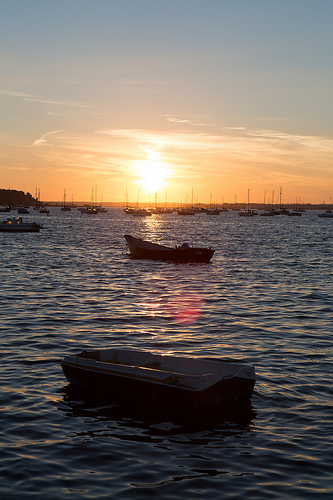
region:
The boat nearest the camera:
[57, 341, 260, 410]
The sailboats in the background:
[0, 183, 332, 221]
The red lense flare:
[162, 288, 209, 328]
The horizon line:
[1, 185, 332, 208]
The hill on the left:
[0, 187, 47, 208]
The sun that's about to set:
[120, 138, 178, 200]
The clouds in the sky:
[0, 73, 332, 192]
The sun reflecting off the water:
[136, 206, 173, 346]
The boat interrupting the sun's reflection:
[120, 230, 217, 264]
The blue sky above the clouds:
[0, 0, 332, 143]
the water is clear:
[226, 466, 237, 478]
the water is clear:
[207, 473, 218, 484]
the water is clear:
[209, 477, 221, 497]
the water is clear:
[218, 479, 222, 490]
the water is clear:
[202, 474, 216, 496]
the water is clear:
[204, 479, 210, 486]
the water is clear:
[201, 479, 206, 487]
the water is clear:
[197, 469, 202, 478]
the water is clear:
[191, 481, 198, 489]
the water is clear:
[211, 467, 218, 487]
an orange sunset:
[2, 0, 332, 203]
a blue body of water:
[2, 201, 327, 491]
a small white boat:
[64, 339, 250, 417]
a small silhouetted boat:
[119, 228, 218, 266]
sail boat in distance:
[79, 184, 94, 212]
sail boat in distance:
[93, 188, 104, 209]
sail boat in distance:
[119, 185, 130, 210]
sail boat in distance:
[131, 184, 145, 215]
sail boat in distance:
[149, 188, 159, 210]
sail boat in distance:
[178, 192, 190, 213]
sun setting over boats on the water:
[117, 148, 189, 219]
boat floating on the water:
[47, 340, 263, 414]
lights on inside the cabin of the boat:
[0, 213, 39, 231]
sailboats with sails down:
[122, 187, 230, 216]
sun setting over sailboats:
[111, 161, 225, 218]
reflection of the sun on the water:
[134, 208, 172, 233]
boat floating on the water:
[117, 231, 220, 267]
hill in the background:
[1, 186, 50, 205]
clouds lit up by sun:
[55, 129, 311, 191]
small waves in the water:
[37, 430, 182, 492]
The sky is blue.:
[165, 16, 291, 51]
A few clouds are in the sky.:
[155, 104, 282, 171]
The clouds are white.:
[193, 113, 290, 162]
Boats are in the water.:
[47, 194, 330, 227]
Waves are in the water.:
[26, 410, 106, 483]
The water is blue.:
[244, 284, 320, 345]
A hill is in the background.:
[0, 180, 63, 213]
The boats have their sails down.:
[77, 183, 301, 222]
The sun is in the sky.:
[116, 149, 183, 194]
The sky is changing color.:
[177, 63, 243, 191]